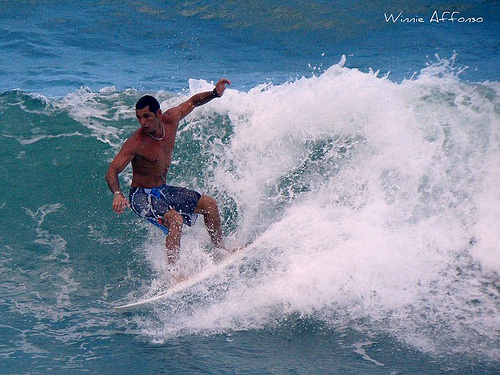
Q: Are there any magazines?
A: No, there are no magazines.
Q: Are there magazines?
A: No, there are no magazines.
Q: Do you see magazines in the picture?
A: No, there are no magazines.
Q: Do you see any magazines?
A: No, there are no magazines.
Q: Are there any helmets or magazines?
A: No, there are no magazines or helmets.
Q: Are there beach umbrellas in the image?
A: No, there are no beach umbrellas.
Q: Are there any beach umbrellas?
A: No, there are no beach umbrellas.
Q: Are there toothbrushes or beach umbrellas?
A: No, there are no beach umbrellas or toothbrushes.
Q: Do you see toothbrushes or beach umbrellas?
A: No, there are no beach umbrellas or toothbrushes.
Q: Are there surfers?
A: Yes, there is a surfer.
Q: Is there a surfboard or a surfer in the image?
A: Yes, there is a surfer.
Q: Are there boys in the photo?
A: No, there are no boys.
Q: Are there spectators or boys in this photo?
A: No, there are no boys or spectators.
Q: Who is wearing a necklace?
A: The surfer is wearing a necklace.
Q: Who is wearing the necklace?
A: The surfer is wearing a necklace.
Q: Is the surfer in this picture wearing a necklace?
A: Yes, the surfer is wearing a necklace.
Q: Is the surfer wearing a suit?
A: No, the surfer is wearing a necklace.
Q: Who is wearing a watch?
A: The surfer is wearing a watch.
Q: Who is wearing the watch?
A: The surfer is wearing a watch.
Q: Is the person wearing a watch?
A: Yes, the surfer is wearing a watch.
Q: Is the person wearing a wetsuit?
A: No, the surfer is wearing a watch.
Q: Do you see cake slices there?
A: No, there are no cake slices.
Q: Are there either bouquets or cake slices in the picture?
A: No, there are no cake slices or bouquets.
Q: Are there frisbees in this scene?
A: No, there are no frisbees.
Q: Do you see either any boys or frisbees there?
A: No, there are no frisbees or boys.